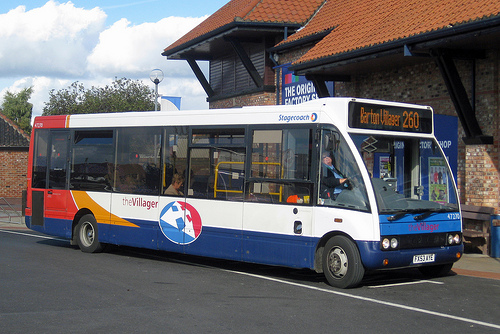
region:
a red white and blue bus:
[20, 85, 464, 304]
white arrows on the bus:
[150, 199, 210, 251]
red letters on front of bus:
[402, 215, 457, 235]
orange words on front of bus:
[353, 106, 424, 131]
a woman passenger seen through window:
[157, 160, 191, 202]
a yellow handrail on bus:
[208, 149, 293, 211]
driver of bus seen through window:
[310, 138, 366, 215]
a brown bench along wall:
[452, 188, 498, 258]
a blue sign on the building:
[265, 59, 339, 126]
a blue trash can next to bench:
[475, 211, 498, 282]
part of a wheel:
[349, 262, 356, 275]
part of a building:
[465, 102, 477, 119]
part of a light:
[381, 233, 391, 259]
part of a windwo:
[386, 157, 395, 175]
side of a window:
[281, 145, 291, 166]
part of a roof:
[357, 46, 370, 64]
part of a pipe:
[376, 53, 385, 64]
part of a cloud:
[170, 95, 173, 100]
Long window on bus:
[30, 122, 56, 208]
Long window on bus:
[42, 122, 70, 202]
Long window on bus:
[71, 125, 116, 192]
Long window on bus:
[113, 122, 167, 205]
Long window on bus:
[156, 120, 200, 213]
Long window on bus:
[187, 120, 248, 223]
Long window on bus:
[244, 112, 323, 194]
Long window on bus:
[319, 117, 366, 228]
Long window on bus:
[331, 117, 441, 223]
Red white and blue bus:
[17, 75, 483, 300]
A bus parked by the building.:
[35, 102, 462, 278]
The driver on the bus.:
[317, 145, 352, 195]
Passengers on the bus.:
[96, 153, 196, 190]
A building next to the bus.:
[201, 17, 488, 107]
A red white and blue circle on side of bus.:
[154, 203, 212, 247]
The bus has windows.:
[38, 133, 210, 183]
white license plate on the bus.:
[408, 249, 443, 259]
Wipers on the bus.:
[373, 200, 438, 222]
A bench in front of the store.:
[451, 189, 491, 243]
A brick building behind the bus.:
[5, 140, 27, 203]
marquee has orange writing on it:
[347, 100, 433, 134]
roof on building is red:
[161, 1, 497, 66]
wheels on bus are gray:
[321, 235, 366, 287]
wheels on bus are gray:
[73, 212, 100, 253]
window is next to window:
[31, 129, 50, 196]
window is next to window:
[48, 127, 69, 186]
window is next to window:
[67, 127, 114, 191]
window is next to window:
[113, 129, 160, 195]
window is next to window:
[162, 129, 190, 194]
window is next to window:
[186, 142, 211, 197]